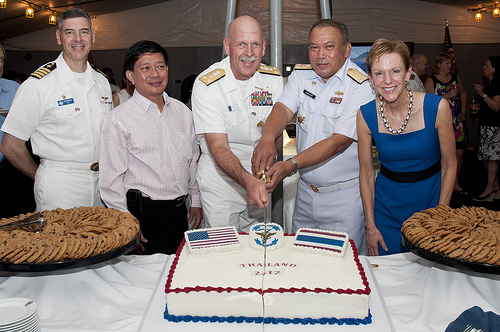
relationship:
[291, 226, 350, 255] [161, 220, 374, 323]
flag on cake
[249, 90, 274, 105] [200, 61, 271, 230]
ribbons on a military uniform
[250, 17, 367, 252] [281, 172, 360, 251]
man of a pants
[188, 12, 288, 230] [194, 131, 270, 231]
man of a pants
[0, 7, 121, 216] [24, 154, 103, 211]
man of a pants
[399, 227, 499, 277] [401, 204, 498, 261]
plate of cookies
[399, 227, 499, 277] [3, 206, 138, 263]
plate of cookies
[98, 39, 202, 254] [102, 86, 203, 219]
man wearing shirt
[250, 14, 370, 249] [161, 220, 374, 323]
man cutting into cake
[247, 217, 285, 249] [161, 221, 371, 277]
logo on cake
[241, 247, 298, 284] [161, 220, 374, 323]
lettering on cake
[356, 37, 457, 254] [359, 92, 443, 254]
woman in dress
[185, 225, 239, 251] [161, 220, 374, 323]
flag decorating cake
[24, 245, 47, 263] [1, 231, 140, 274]
cookie lying on platter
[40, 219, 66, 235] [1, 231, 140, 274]
cookie lying on platter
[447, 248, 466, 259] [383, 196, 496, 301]
cookie lying on platter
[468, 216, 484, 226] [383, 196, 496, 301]
cookie lying on platter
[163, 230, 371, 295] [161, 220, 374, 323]
border lining cake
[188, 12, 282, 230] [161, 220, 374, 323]
man cutting cake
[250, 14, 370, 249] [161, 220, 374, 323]
man cutting cake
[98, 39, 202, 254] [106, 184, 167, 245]
man wearing pants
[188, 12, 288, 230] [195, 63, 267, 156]
man wearing white shirt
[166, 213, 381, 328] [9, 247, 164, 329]
cake sitting on table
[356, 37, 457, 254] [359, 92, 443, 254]
woman wearing dress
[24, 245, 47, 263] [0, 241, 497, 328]
cookie on table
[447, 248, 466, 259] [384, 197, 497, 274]
cookie on tray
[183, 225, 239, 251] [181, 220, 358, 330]
flag on cake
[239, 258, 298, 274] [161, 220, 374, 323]
writing on cake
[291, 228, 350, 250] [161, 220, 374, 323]
flag on cake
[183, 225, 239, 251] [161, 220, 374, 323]
flag on cake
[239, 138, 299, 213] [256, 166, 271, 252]
hands holding knife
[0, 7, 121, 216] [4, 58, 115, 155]
man wears shirt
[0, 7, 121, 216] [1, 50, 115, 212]
man wearing uniform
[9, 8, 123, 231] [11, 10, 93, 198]
man wearing pants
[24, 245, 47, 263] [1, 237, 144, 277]
cookie on tray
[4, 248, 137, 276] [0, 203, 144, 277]
tray full of cookies